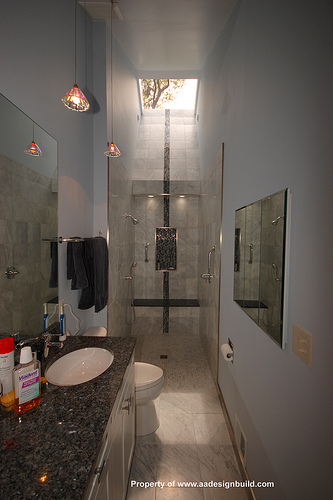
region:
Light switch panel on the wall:
[293, 324, 310, 364]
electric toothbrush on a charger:
[55, 303, 71, 342]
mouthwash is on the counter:
[10, 351, 41, 410]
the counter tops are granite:
[36, 437, 78, 496]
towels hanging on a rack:
[60, 237, 109, 302]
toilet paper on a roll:
[221, 338, 236, 361]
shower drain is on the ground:
[161, 348, 177, 366]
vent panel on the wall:
[230, 411, 248, 465]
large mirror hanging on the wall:
[229, 210, 298, 327]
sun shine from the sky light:
[153, 380, 211, 453]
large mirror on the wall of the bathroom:
[226, 184, 292, 350]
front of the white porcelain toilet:
[138, 360, 168, 439]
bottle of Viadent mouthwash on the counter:
[12, 346, 45, 414]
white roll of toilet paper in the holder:
[220, 335, 237, 364]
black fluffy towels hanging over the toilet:
[64, 232, 114, 317]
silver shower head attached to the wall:
[121, 206, 140, 229]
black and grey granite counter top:
[7, 423, 90, 493]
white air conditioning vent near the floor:
[231, 412, 253, 465]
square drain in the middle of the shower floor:
[157, 350, 168, 361]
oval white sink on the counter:
[44, 344, 116, 392]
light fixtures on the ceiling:
[61, 1, 119, 159]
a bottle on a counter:
[13, 345, 42, 412]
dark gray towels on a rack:
[66, 234, 108, 312]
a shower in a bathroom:
[109, 146, 219, 383]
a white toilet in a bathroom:
[81, 327, 161, 437]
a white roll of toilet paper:
[220, 341, 233, 362]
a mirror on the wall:
[232, 189, 288, 349]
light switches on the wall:
[292, 325, 310, 366]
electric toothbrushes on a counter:
[43, 300, 66, 341]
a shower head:
[124, 211, 137, 227]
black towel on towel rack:
[79, 226, 132, 320]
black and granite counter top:
[75, 414, 85, 420]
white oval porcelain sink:
[78, 359, 94, 366]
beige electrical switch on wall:
[292, 323, 322, 376]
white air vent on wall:
[228, 417, 257, 465]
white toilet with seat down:
[142, 359, 148, 388]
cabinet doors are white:
[111, 434, 123, 462]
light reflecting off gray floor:
[178, 394, 212, 455]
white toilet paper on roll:
[218, 339, 245, 362]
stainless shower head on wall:
[124, 203, 134, 224]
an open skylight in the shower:
[136, 71, 199, 124]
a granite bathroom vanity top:
[0, 413, 97, 498]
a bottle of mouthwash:
[12, 345, 42, 412]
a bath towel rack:
[58, 233, 106, 245]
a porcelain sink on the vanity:
[44, 345, 113, 387]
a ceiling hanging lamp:
[60, 1, 92, 113]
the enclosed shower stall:
[108, 76, 221, 358]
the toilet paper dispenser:
[219, 335, 235, 362]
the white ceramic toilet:
[134, 360, 163, 437]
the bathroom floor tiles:
[165, 369, 218, 479]